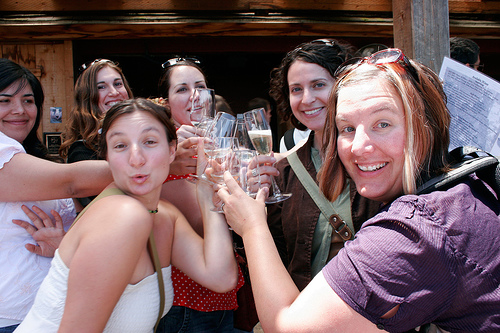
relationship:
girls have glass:
[14, 55, 449, 264] [244, 108, 294, 204]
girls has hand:
[217, 49, 500, 333] [215, 164, 279, 242]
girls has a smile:
[217, 49, 500, 333] [342, 150, 406, 186]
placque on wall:
[33, 124, 67, 160] [20, 48, 83, 152]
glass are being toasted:
[244, 108, 294, 204] [170, 97, 364, 283]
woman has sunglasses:
[152, 63, 238, 143] [157, 55, 216, 75]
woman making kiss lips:
[99, 95, 175, 215] [127, 163, 159, 195]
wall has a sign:
[20, 48, 83, 152] [46, 132, 73, 163]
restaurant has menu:
[12, 7, 498, 236] [435, 54, 498, 172]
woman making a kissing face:
[99, 95, 175, 215] [111, 134, 171, 185]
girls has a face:
[217, 49, 500, 333] [324, 86, 413, 210]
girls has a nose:
[217, 49, 500, 333] [350, 129, 375, 155]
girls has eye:
[217, 49, 500, 333] [341, 126, 356, 133]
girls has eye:
[217, 49, 500, 333] [341, 122, 357, 136]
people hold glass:
[14, 55, 449, 264] [244, 108, 294, 204]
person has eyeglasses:
[152, 63, 238, 143] [157, 55, 216, 75]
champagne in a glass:
[249, 125, 276, 154] [235, 115, 297, 204]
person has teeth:
[257, 24, 397, 160] [296, 104, 332, 122]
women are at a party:
[14, 55, 449, 264] [17, 37, 474, 300]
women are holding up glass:
[14, 55, 449, 264] [244, 108, 294, 204]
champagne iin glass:
[249, 125, 276, 154] [235, 115, 297, 204]